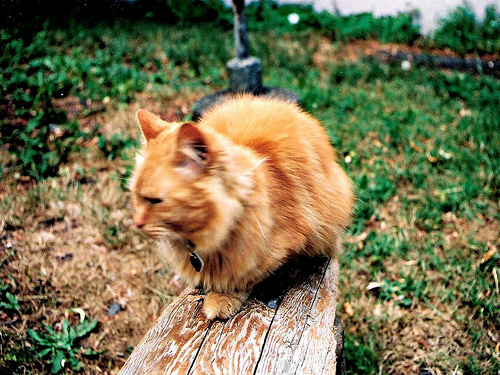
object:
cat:
[129, 89, 357, 320]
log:
[117, 281, 340, 375]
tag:
[189, 252, 204, 274]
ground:
[1, 0, 499, 374]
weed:
[27, 319, 99, 373]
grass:
[0, 19, 499, 374]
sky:
[308, 2, 498, 36]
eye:
[144, 196, 163, 205]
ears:
[171, 116, 211, 165]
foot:
[200, 290, 241, 321]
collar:
[186, 237, 196, 248]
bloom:
[288, 12, 300, 23]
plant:
[261, 8, 314, 42]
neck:
[167, 142, 274, 253]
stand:
[191, 1, 299, 107]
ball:
[399, 59, 411, 71]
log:
[359, 50, 499, 72]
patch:
[1, 140, 127, 372]